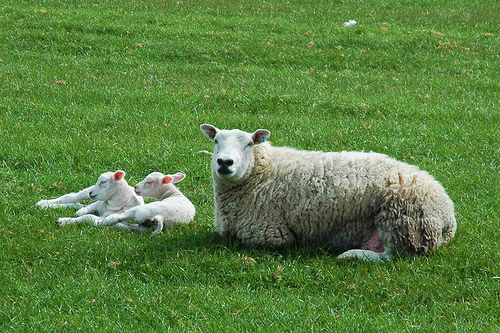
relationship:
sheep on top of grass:
[199, 123, 458, 259] [2, 1, 500, 332]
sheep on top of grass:
[97, 171, 197, 236] [2, 1, 500, 332]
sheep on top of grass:
[36, 169, 145, 225] [2, 1, 500, 332]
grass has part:
[2, 1, 500, 332] [2, 0, 76, 50]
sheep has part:
[199, 123, 458, 259] [282, 148, 321, 176]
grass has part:
[2, 1, 500, 332] [79, 0, 154, 48]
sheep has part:
[199, 123, 458, 259] [327, 151, 368, 178]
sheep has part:
[199, 123, 458, 259] [375, 154, 416, 186]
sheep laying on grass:
[199, 123, 458, 259] [2, 1, 500, 332]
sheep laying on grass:
[97, 171, 197, 236] [2, 1, 500, 332]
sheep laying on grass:
[36, 169, 145, 225] [2, 1, 500, 332]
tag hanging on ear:
[259, 135, 267, 143] [253, 128, 274, 144]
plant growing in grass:
[344, 17, 359, 29] [2, 1, 500, 332]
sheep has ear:
[36, 169, 145, 225] [113, 170, 128, 183]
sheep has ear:
[199, 123, 458, 259] [253, 128, 274, 144]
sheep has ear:
[97, 171, 197, 236] [160, 174, 175, 188]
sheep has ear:
[97, 171, 197, 236] [173, 172, 188, 182]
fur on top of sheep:
[214, 145, 458, 249] [199, 123, 458, 259]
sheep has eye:
[199, 123, 458, 259] [212, 136, 219, 146]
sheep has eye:
[199, 123, 458, 259] [247, 141, 255, 151]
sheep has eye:
[97, 171, 197, 236] [145, 179, 157, 185]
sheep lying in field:
[34, 169, 145, 228] [1, 1, 484, 121]